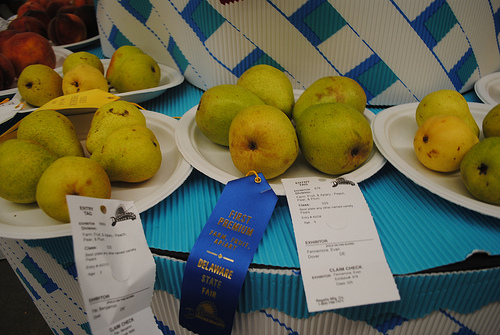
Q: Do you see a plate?
A: Yes, there is a plate.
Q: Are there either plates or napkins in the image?
A: Yes, there is a plate.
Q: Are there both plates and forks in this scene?
A: No, there is a plate but no forks.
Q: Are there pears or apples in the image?
A: Yes, there is a pear.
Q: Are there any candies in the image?
A: No, there are no candies.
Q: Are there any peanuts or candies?
A: No, there are no candies or peanuts.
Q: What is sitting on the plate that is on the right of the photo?
A: The pear is sitting on the plate.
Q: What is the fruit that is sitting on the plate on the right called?
A: The fruit is a pear.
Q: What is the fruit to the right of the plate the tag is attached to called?
A: The fruit is a pear.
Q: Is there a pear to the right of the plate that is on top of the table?
A: Yes, there is a pear to the right of the plate.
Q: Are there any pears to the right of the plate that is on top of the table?
A: Yes, there is a pear to the right of the plate.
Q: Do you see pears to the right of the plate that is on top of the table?
A: Yes, there is a pear to the right of the plate.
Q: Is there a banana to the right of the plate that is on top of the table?
A: No, there is a pear to the right of the plate.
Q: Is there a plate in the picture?
A: Yes, there is a plate.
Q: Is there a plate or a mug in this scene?
A: Yes, there is a plate.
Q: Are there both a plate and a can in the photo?
A: No, there is a plate but no cans.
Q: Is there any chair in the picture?
A: No, there are no chairs.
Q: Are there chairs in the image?
A: No, there are no chairs.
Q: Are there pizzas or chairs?
A: No, there are no chairs or pizzas.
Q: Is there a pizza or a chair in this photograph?
A: No, there are no chairs or pizzas.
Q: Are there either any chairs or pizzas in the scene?
A: No, there are no chairs or pizzas.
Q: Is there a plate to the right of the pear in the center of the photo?
A: Yes, there is a plate to the right of the pear.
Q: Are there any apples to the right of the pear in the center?
A: No, there is a plate to the right of the pear.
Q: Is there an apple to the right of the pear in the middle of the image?
A: No, there is a plate to the right of the pear.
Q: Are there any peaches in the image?
A: Yes, there is a peach.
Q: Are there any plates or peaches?
A: Yes, there is a peach.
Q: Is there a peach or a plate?
A: Yes, there is a peach.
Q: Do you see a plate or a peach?
A: Yes, there is a peach.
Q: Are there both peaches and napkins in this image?
A: No, there is a peach but no napkins.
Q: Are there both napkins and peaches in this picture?
A: No, there is a peach but no napkins.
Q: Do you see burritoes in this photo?
A: No, there are no burritoes.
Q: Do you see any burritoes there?
A: No, there are no burritoes.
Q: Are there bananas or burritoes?
A: No, there are no burritoes or bananas.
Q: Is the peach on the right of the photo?
A: No, the peach is on the left of the image.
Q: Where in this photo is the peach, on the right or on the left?
A: The peach is on the left of the image.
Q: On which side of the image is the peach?
A: The peach is on the left of the image.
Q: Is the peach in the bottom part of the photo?
A: No, the peach is in the top of the image.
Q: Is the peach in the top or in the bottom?
A: The peach is in the top of the image.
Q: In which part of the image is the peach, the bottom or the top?
A: The peach is in the top of the image.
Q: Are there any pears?
A: Yes, there is a pear.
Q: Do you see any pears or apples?
A: Yes, there is a pear.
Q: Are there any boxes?
A: No, there are no boxes.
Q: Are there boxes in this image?
A: No, there are no boxes.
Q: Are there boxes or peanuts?
A: No, there are no boxes or peanuts.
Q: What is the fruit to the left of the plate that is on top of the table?
A: The fruit is a pear.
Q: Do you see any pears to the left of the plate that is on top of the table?
A: Yes, there is a pear to the left of the plate.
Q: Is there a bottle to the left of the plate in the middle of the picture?
A: No, there is a pear to the left of the plate.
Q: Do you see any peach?
A: Yes, there is a peach.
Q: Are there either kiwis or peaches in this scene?
A: Yes, there is a peach.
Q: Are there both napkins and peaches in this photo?
A: No, there is a peach but no napkins.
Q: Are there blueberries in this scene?
A: No, there are no blueberries.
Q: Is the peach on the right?
A: No, the peach is on the left of the image.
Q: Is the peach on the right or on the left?
A: The peach is on the left of the image.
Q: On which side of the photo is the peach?
A: The peach is on the left of the image.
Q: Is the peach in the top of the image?
A: Yes, the peach is in the top of the image.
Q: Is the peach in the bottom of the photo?
A: No, the peach is in the top of the image.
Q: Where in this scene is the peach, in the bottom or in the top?
A: The peach is in the top of the image.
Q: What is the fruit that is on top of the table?
A: The fruit is a peach.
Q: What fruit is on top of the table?
A: The fruit is a peach.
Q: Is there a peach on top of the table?
A: Yes, there is a peach on top of the table.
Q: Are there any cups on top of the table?
A: No, there is a peach on top of the table.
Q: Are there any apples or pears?
A: Yes, there is a pear.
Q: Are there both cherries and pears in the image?
A: No, there is a pear but no cherries.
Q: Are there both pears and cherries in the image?
A: No, there is a pear but no cherries.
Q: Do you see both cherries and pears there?
A: No, there is a pear but no cherries.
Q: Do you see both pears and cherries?
A: No, there is a pear but no cherries.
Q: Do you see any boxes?
A: No, there are no boxes.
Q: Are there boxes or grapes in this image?
A: No, there are no boxes or grapes.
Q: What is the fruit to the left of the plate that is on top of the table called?
A: The fruit is a pear.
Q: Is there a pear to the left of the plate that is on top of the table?
A: Yes, there is a pear to the left of the plate.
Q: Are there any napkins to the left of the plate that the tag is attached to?
A: No, there is a pear to the left of the plate.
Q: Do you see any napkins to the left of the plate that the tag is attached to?
A: No, there is a pear to the left of the plate.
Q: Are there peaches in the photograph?
A: Yes, there is a peach.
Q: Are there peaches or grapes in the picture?
A: Yes, there is a peach.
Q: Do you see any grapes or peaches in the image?
A: Yes, there is a peach.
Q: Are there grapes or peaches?
A: Yes, there is a peach.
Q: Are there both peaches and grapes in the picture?
A: No, there is a peach but no grapes.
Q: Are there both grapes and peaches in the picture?
A: No, there is a peach but no grapes.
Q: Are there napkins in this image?
A: No, there are no napkins.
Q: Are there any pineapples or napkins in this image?
A: No, there are no napkins or pineapples.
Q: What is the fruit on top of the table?
A: The fruit is a peach.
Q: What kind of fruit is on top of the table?
A: The fruit is a peach.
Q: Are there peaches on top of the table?
A: Yes, there is a peach on top of the table.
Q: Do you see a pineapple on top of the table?
A: No, there is a peach on top of the table.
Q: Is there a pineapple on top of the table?
A: No, there is a peach on top of the table.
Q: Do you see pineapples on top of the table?
A: No, there is a peach on top of the table.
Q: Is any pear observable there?
A: Yes, there is a pear.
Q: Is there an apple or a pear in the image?
A: Yes, there is a pear.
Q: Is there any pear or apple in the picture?
A: Yes, there is a pear.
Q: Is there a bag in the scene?
A: No, there are no bags.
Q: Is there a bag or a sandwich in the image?
A: No, there are no bags or sandwiches.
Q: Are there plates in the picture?
A: Yes, there is a plate.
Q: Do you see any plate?
A: Yes, there is a plate.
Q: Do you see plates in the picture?
A: Yes, there is a plate.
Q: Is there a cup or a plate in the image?
A: Yes, there is a plate.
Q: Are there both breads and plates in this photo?
A: No, there is a plate but no breads.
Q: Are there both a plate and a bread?
A: No, there is a plate but no breads.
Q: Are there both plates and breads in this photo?
A: No, there is a plate but no breads.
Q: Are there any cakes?
A: No, there are no cakes.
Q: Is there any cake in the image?
A: No, there are no cakes.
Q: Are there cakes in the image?
A: No, there are no cakes.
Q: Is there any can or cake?
A: No, there are no cakes or cans.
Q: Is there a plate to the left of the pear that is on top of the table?
A: Yes, there is a plate to the left of the pear.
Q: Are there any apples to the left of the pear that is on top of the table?
A: No, there is a plate to the left of the pear.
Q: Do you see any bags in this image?
A: No, there are no bags.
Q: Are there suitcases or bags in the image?
A: No, there are no bags or suitcases.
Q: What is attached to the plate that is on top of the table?
A: The tag is attached to the plate.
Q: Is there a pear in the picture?
A: Yes, there is a pear.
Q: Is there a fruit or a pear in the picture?
A: Yes, there is a pear.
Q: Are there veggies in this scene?
A: No, there are no veggies.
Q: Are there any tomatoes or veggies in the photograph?
A: No, there are no veggies or tomatoes.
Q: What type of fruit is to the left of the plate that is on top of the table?
A: The fruit is a pear.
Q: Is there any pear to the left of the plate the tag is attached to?
A: Yes, there is a pear to the left of the plate.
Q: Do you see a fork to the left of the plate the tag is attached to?
A: No, there is a pear to the left of the plate.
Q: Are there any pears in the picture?
A: Yes, there is a pear.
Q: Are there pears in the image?
A: Yes, there is a pear.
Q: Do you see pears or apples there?
A: Yes, there is a pear.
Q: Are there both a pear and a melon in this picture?
A: No, there is a pear but no melons.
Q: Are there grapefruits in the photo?
A: No, there are no grapefruits.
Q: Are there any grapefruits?
A: No, there are no grapefruits.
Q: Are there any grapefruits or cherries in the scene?
A: No, there are no grapefruits or cherries.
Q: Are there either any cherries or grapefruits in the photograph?
A: No, there are no grapefruits or cherries.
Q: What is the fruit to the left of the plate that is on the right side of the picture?
A: The fruit is a pear.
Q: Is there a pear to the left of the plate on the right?
A: Yes, there is a pear to the left of the plate.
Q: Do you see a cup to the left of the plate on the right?
A: No, there is a pear to the left of the plate.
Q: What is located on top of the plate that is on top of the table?
A: The pear is on top of the plate.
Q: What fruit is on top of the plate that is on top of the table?
A: The fruit is a pear.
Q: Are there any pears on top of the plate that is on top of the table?
A: Yes, there is a pear on top of the plate.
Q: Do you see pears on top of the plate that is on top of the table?
A: Yes, there is a pear on top of the plate.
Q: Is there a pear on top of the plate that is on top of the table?
A: Yes, there is a pear on top of the plate.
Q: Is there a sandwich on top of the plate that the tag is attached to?
A: No, there is a pear on top of the plate.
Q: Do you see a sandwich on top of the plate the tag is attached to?
A: No, there is a pear on top of the plate.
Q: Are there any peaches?
A: Yes, there is a peach.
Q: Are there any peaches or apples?
A: Yes, there is a peach.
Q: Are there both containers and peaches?
A: No, there is a peach but no containers.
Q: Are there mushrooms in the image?
A: No, there are no mushrooms.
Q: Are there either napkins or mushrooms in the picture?
A: No, there are no mushrooms or napkins.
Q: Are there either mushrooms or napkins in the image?
A: No, there are no mushrooms or napkins.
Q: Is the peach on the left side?
A: Yes, the peach is on the left of the image.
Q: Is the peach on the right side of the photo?
A: No, the peach is on the left of the image.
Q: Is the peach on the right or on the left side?
A: The peach is on the left of the image.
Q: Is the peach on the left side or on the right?
A: The peach is on the left of the image.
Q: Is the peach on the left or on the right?
A: The peach is on the left of the image.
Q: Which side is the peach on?
A: The peach is on the left of the image.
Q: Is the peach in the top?
A: Yes, the peach is in the top of the image.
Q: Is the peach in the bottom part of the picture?
A: No, the peach is in the top of the image.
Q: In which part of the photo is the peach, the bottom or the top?
A: The peach is in the top of the image.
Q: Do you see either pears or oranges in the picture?
A: Yes, there is a pear.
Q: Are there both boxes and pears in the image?
A: No, there is a pear but no boxes.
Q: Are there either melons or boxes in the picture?
A: No, there are no boxes or melons.